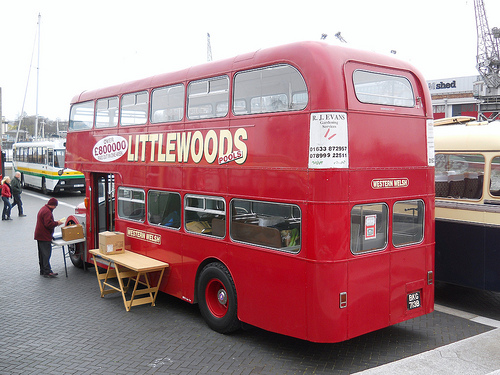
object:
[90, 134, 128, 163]
sign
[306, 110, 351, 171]
sign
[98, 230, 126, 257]
box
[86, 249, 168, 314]
table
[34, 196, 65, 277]
man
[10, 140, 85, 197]
bus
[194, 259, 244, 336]
tire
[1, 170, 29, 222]
people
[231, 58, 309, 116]
window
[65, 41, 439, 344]
bus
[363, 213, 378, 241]
sign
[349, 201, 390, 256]
window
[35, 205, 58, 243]
coat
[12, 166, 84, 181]
stripes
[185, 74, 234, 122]
window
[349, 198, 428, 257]
windows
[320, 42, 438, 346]
back of  bus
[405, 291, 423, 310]
license plate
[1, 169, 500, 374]
parking lot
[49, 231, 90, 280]
table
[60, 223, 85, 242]
box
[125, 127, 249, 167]
advertisment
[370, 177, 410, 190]
logo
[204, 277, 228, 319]
tire rim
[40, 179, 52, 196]
tire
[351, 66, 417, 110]
window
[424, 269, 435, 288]
tail light